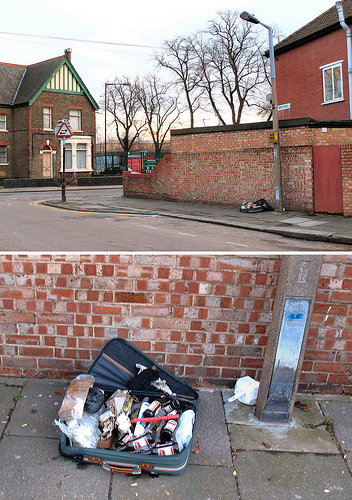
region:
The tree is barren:
[100, 81, 139, 153]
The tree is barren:
[127, 76, 173, 149]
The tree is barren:
[165, 41, 201, 124]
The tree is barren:
[188, 31, 243, 124]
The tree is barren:
[238, 43, 274, 123]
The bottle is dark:
[145, 391, 168, 416]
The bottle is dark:
[163, 409, 177, 437]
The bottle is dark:
[135, 441, 179, 459]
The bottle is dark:
[115, 434, 156, 453]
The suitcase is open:
[51, 328, 211, 479]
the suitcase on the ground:
[51, 342, 202, 472]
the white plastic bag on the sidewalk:
[226, 370, 260, 410]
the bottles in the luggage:
[124, 396, 181, 453]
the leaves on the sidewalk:
[191, 438, 349, 496]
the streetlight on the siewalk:
[232, 4, 284, 213]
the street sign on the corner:
[48, 118, 79, 203]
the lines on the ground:
[136, 214, 248, 248]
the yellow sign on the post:
[266, 126, 281, 146]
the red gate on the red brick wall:
[310, 140, 345, 218]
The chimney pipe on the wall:
[334, 0, 350, 120]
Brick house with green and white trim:
[0, 45, 101, 188]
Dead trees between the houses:
[93, 2, 284, 179]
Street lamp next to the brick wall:
[236, 6, 285, 216]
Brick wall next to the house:
[117, 111, 347, 215]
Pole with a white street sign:
[49, 112, 70, 200]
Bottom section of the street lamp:
[248, 250, 322, 421]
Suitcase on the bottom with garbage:
[43, 330, 199, 475]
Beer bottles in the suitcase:
[110, 387, 183, 454]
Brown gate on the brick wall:
[306, 140, 346, 219]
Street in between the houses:
[1, 181, 349, 252]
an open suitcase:
[53, 337, 195, 473]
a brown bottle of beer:
[160, 408, 179, 438]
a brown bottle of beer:
[140, 440, 178, 455]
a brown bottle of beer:
[115, 432, 154, 451]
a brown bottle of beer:
[114, 427, 133, 446]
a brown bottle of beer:
[143, 392, 166, 416]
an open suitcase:
[239, 197, 270, 213]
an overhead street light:
[238, 10, 272, 29]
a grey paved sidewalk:
[40, 196, 351, 241]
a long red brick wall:
[122, 146, 312, 212]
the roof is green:
[79, 82, 91, 98]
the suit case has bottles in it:
[142, 423, 166, 443]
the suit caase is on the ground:
[172, 463, 194, 479]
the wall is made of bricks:
[215, 155, 233, 181]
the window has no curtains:
[325, 76, 343, 96]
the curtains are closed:
[68, 148, 86, 159]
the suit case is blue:
[100, 365, 114, 377]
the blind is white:
[71, 113, 78, 125]